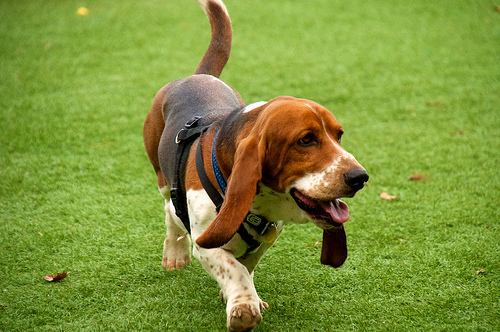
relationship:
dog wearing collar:
[140, 0, 368, 332] [208, 118, 282, 237]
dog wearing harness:
[140, 0, 368, 332] [167, 104, 261, 263]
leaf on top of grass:
[43, 266, 67, 286] [0, 0, 498, 332]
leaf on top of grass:
[378, 187, 397, 204] [0, 0, 498, 332]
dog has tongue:
[140, 0, 368, 332] [318, 197, 350, 226]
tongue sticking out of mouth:
[318, 197, 350, 226] [287, 183, 354, 228]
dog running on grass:
[140, 0, 368, 332] [0, 0, 498, 332]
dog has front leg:
[140, 0, 368, 332] [189, 192, 269, 330]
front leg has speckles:
[189, 192, 269, 330] [191, 220, 255, 304]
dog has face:
[140, 0, 368, 332] [286, 111, 370, 227]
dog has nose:
[140, 0, 368, 332] [343, 163, 369, 193]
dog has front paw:
[140, 0, 368, 332] [222, 298, 270, 331]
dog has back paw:
[140, 0, 368, 332] [159, 237, 193, 270]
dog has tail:
[140, 0, 368, 332] [191, 0, 233, 80]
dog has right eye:
[140, 0, 368, 332] [295, 127, 317, 148]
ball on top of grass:
[74, 5, 90, 20] [0, 0, 498, 332]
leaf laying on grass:
[43, 266, 67, 286] [0, 0, 498, 332]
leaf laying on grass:
[378, 187, 397, 204] [0, 0, 498, 332]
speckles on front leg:
[191, 220, 255, 304] [189, 192, 269, 330]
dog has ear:
[140, 0, 368, 332] [195, 135, 262, 249]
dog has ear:
[140, 0, 368, 332] [314, 218, 349, 268]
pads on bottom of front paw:
[231, 310, 261, 330] [222, 298, 270, 331]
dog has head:
[140, 0, 368, 332] [251, 92, 368, 233]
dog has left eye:
[140, 0, 368, 332] [335, 127, 346, 143]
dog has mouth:
[140, 0, 368, 332] [287, 183, 354, 228]